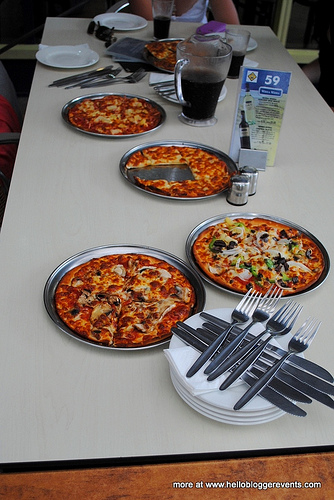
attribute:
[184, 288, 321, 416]
forks — silver, shiny, steel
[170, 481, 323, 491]
letters — white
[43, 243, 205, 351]
pan — metal, grey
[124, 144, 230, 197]
pizza — missing some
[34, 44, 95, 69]
plate — empty